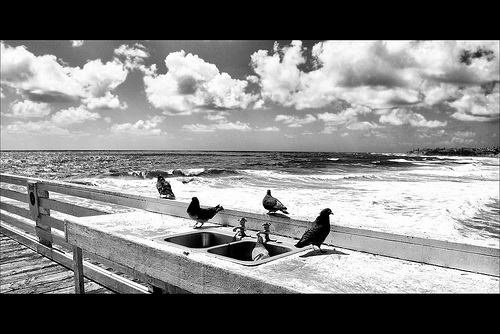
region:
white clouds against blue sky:
[14, 51, 78, 92]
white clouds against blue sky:
[46, 91, 108, 126]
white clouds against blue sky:
[114, 64, 195, 111]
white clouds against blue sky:
[160, 90, 252, 137]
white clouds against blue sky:
[210, 44, 278, 111]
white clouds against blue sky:
[300, 65, 384, 103]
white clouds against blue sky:
[312, 83, 415, 148]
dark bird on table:
[142, 166, 175, 203]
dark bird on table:
[246, 180, 282, 207]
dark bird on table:
[288, 200, 332, 264]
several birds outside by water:
[145, 168, 340, 248]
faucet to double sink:
[229, 214, 276, 242]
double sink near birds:
[165, 230, 298, 270]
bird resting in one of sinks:
[245, 233, 270, 273]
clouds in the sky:
[0, 39, 498, 128]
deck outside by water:
[2, 232, 66, 291]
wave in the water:
[186, 160, 418, 182]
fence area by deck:
[3, 167, 62, 252]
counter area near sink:
[72, 205, 164, 237]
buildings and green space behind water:
[411, 143, 498, 156]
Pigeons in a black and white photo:
[158, 169, 350, 262]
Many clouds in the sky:
[51, 47, 454, 157]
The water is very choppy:
[57, 117, 134, 182]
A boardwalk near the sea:
[12, 127, 83, 289]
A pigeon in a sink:
[236, 219, 276, 270]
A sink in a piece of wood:
[127, 199, 324, 288]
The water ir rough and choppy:
[321, 140, 472, 227]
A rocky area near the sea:
[391, 129, 496, 166]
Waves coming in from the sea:
[188, 148, 334, 183]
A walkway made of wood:
[5, 224, 67, 288]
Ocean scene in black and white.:
[0, 40, 498, 290]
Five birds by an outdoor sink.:
[152, 175, 334, 290]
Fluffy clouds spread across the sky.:
[0, 40, 499, 152]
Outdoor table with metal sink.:
[64, 207, 496, 293]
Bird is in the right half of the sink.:
[156, 227, 317, 266]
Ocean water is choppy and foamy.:
[3, 150, 499, 250]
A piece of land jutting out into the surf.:
[408, 147, 499, 159]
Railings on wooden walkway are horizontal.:
[0, 174, 146, 296]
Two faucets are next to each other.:
[231, 215, 271, 241]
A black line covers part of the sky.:
[1, 0, 498, 152]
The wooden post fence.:
[2, 168, 205, 279]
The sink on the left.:
[183, 223, 231, 251]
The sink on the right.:
[215, 228, 282, 268]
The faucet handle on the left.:
[231, 208, 251, 233]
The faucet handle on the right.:
[252, 222, 274, 237]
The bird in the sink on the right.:
[241, 222, 269, 270]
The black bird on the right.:
[295, 200, 340, 255]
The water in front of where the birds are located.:
[18, 127, 498, 247]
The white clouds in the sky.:
[1, 38, 498, 138]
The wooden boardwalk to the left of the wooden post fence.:
[2, 235, 112, 305]